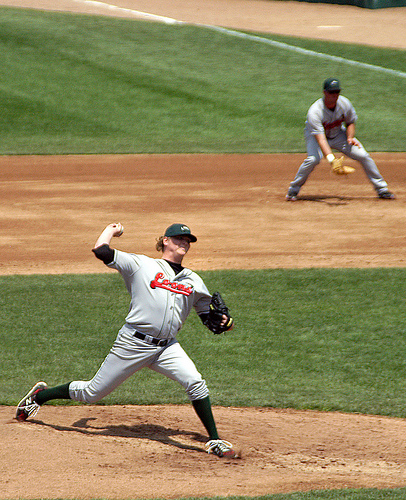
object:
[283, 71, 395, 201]
player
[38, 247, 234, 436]
uniform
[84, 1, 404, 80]
white line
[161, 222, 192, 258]
head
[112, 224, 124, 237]
baseball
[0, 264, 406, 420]
grass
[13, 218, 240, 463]
man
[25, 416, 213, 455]
shadow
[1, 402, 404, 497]
dirt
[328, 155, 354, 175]
mitt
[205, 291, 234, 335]
mitt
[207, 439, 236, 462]
foot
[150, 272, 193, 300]
writing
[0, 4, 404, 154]
grass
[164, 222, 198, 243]
hat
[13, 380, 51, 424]
foot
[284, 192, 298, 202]
foot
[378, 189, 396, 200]
foot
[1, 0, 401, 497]
field